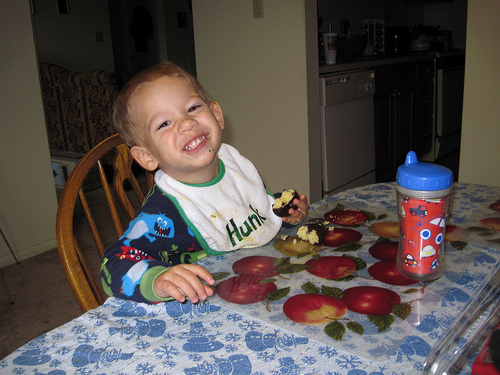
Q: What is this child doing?
A: Eating.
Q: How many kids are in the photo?
A: One.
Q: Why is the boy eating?
A: Hungry.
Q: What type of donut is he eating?
A: Chocolate.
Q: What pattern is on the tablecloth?
A: Snowmen.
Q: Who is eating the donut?
A: Boy.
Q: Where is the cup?
A: Table.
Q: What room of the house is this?
A: Dining room.